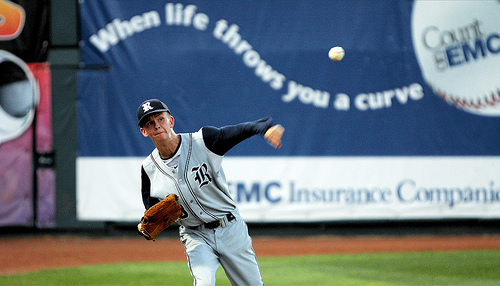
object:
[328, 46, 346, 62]
baseball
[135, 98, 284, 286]
pitcher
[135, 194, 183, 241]
baseball glove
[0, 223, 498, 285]
baseball field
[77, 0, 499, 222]
advertisement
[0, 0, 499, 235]
wall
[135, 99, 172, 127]
cap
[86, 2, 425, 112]
text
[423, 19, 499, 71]
text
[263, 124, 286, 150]
hand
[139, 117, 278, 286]
uniform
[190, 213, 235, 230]
belt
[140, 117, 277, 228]
jersey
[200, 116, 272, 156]
sleeve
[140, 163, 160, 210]
sleeve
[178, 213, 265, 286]
pants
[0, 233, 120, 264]
dirt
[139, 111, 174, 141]
face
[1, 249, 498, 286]
grass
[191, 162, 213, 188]
letter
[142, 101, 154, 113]
letter